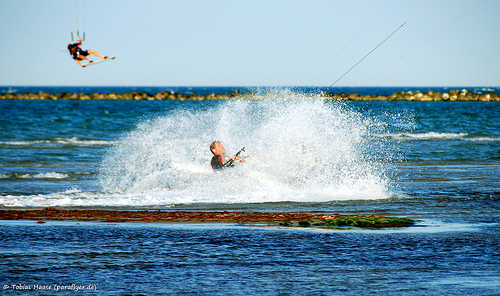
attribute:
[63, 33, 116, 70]
man — wind surfing, parasailing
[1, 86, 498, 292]
water — dark blue, blue, white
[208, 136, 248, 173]
man — wet, standing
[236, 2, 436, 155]
rope — gray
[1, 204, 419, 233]
moat — small, floating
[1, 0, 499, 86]
sky — blue, light blue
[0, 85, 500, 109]
barrier — bunch, rock, long, rocky, coral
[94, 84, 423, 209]
splash — big, white, large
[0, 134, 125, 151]
wave — moving, small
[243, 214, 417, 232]
part — green